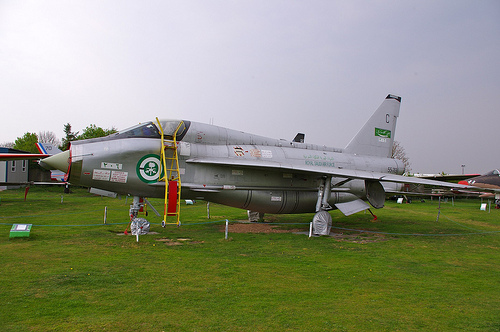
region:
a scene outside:
[10, 22, 495, 322]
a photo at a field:
[5, 9, 495, 329]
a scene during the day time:
[16, 13, 494, 330]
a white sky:
[7, 8, 494, 163]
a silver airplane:
[17, 86, 487, 233]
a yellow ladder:
[133, 113, 203, 231]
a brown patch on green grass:
[205, 208, 397, 268]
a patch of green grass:
[6, 175, 498, 326]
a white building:
[0, 132, 70, 203]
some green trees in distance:
[3, 96, 161, 168]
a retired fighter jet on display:
[21, 80, 482, 255]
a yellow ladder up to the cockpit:
[158, 138, 185, 234]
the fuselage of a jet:
[120, 110, 355, 216]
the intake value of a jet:
[30, 136, 76, 186]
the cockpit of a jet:
[127, 114, 193, 138]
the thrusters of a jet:
[386, 155, 410, 197]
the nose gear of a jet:
[126, 191, 151, 238]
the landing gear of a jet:
[312, 177, 337, 236]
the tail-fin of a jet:
[345, 84, 410, 150]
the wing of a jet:
[223, 160, 498, 200]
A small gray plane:
[35, 89, 498, 238]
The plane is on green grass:
[1, 90, 498, 330]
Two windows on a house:
[6, 152, 30, 173]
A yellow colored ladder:
[150, 114, 185, 232]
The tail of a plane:
[342, 90, 405, 158]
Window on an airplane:
[112, 114, 190, 142]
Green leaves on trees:
[9, 119, 121, 156]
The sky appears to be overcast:
[1, 3, 498, 175]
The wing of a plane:
[183, 152, 498, 199]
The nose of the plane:
[33, 140, 100, 193]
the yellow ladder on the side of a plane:
[155, 127, 187, 227]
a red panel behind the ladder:
[167, 178, 176, 218]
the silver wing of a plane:
[198, 150, 488, 191]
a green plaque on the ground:
[7, 216, 36, 238]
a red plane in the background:
[415, 168, 494, 198]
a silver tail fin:
[344, 91, 402, 151]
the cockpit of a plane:
[147, 119, 187, 135]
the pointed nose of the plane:
[39, 153, 72, 168]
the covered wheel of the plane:
[314, 208, 335, 238]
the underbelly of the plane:
[181, 180, 321, 211]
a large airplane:
[36, 95, 424, 230]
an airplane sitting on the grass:
[53, 112, 433, 218]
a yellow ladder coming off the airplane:
[162, 141, 182, 226]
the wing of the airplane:
[200, 140, 495, 195]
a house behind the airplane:
[1, 145, 44, 188]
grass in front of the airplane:
[25, 250, 490, 326]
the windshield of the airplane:
[150, 120, 182, 131]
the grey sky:
[41, 25, 362, 98]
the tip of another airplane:
[458, 166, 495, 192]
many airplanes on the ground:
[76, 92, 492, 189]